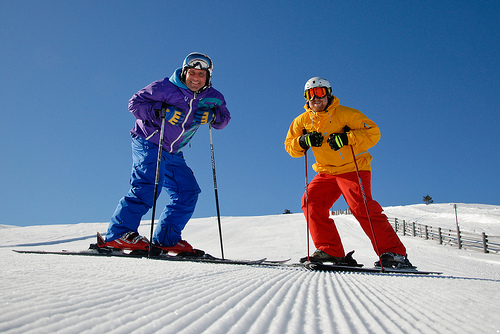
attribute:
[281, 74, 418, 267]
man — skiing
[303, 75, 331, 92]
helmet — white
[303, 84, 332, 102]
protective goggles — orange, on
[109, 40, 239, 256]
man — skiing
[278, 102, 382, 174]
jacket — yellow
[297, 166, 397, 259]
ski pants — red, orange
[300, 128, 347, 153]
gloves — yellow, black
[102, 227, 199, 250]
boots — red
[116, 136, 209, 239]
ski pants — blue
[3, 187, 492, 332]
snow — track marked, white, freshly plowed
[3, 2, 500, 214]
sky — blue, clear, crystal clear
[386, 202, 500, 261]
fence — wooden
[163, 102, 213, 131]
gloves — blue, yellow